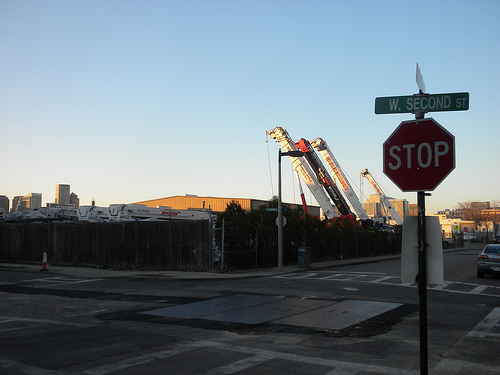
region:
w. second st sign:
[371, 88, 468, 114]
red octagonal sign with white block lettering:
[376, 115, 452, 191]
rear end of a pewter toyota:
[470, 240, 495, 275]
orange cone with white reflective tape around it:
[35, 245, 50, 271]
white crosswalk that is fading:
[265, 265, 496, 297]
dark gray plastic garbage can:
[291, 240, 311, 270]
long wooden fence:
[0, 215, 210, 265]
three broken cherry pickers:
[262, 122, 369, 220]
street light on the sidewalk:
[273, 146, 304, 275]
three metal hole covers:
[133, 289, 407, 336]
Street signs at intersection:
[363, 57, 478, 115]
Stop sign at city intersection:
[370, 115, 460, 197]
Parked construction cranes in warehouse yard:
[256, 120, 397, 230]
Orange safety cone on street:
[30, 242, 55, 272]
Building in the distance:
[435, 195, 496, 240]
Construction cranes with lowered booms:
[76, 200, 216, 225]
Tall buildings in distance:
[45, 176, 80, 206]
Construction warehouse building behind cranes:
[120, 185, 325, 235]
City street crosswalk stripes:
[270, 260, 495, 300]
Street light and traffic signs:
[272, 143, 307, 278]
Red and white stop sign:
[380, 118, 458, 195]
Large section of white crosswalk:
[283, 266, 398, 293]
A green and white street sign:
[374, 90, 472, 117]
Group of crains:
[274, 122, 370, 217]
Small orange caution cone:
[38, 246, 56, 275]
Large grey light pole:
[274, 148, 303, 272]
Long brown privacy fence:
[58, 223, 211, 273]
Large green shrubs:
[215, 203, 253, 267]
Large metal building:
[140, 191, 271, 211]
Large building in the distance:
[2, 181, 87, 212]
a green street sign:
[371, 87, 487, 117]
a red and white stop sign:
[375, 113, 469, 197]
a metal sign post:
[407, 183, 444, 372]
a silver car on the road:
[473, 236, 498, 265]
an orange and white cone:
[35, 244, 49, 271]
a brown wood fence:
[9, 209, 213, 269]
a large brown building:
[128, 190, 329, 223]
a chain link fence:
[220, 212, 401, 264]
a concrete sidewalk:
[4, 254, 250, 284]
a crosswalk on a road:
[276, 257, 498, 309]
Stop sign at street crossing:
[369, 57, 471, 372]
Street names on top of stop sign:
[368, 58, 477, 118]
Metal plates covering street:
[137, 283, 409, 346]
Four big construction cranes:
[262, 120, 404, 227]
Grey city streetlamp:
[260, 144, 310, 273]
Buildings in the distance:
[0, 177, 100, 220]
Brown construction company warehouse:
[125, 189, 322, 227]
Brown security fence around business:
[0, 211, 221, 273]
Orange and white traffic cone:
[32, 244, 59, 285]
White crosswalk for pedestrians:
[270, 263, 498, 299]